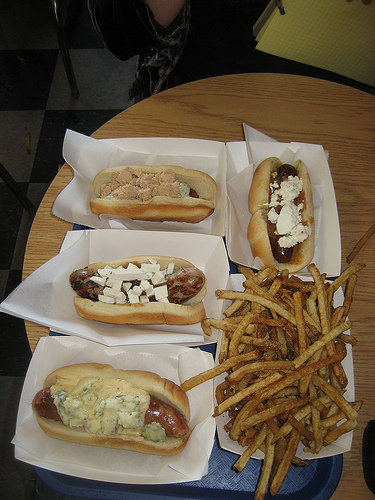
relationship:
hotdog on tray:
[245, 153, 317, 275] [33, 221, 342, 498]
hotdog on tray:
[84, 166, 220, 219] [33, 221, 342, 498]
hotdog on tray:
[30, 366, 203, 453] [33, 221, 342, 498]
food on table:
[79, 152, 225, 216] [31, 70, 367, 476]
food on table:
[247, 147, 330, 272] [31, 70, 367, 476]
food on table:
[212, 257, 364, 456] [31, 70, 367, 476]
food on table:
[56, 244, 240, 324] [31, 70, 367, 476]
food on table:
[37, 353, 204, 466] [31, 70, 367, 476]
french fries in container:
[238, 274, 336, 359] [199, 244, 261, 343]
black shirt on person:
[92, 3, 222, 75] [90, 5, 245, 96]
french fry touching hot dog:
[178, 348, 260, 393] [69, 253, 209, 325]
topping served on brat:
[98, 167, 189, 201] [88, 162, 220, 212]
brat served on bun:
[88, 162, 220, 212] [88, 164, 217, 222]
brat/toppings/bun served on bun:
[30, 383, 190, 440] [33, 359, 194, 457]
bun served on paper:
[33, 359, 194, 457] [9, 335, 213, 477]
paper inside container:
[9, 335, 213, 477] [11, 331, 212, 488]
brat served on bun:
[187, 188, 197, 198] [88, 164, 217, 222]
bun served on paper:
[88, 164, 217, 222] [50, 128, 221, 234]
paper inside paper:
[50, 128, 221, 234] [9, 334, 217, 484]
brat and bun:
[269, 164, 301, 260] [244, 153, 316, 276]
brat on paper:
[269, 164, 301, 260] [226, 121, 326, 276]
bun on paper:
[244, 153, 316, 276] [226, 121, 326, 276]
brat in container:
[269, 164, 301, 260] [227, 136, 345, 275]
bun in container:
[244, 153, 316, 276] [227, 136, 345, 275]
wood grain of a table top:
[22, 72, 373, 498] [20, 70, 374, 498]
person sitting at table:
[97, 0, 217, 83] [31, 70, 367, 476]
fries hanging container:
[237, 417, 327, 495] [222, 272, 359, 460]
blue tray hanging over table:
[36, 206, 347, 496] [31, 70, 367, 476]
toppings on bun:
[88, 399, 129, 425] [142, 433, 176, 452]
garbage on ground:
[23, 130, 32, 154] [1, 0, 138, 498]